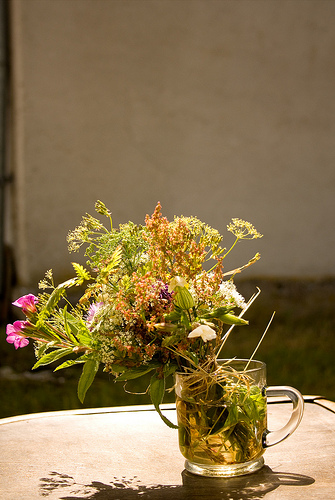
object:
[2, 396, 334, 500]
surface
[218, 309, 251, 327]
leaf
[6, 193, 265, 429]
flowers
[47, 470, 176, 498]
white wall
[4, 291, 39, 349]
purple flower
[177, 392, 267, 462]
water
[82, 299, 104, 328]
purple flower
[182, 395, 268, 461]
stem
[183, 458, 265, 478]
base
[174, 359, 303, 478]
cup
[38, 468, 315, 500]
shadow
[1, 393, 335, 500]
table